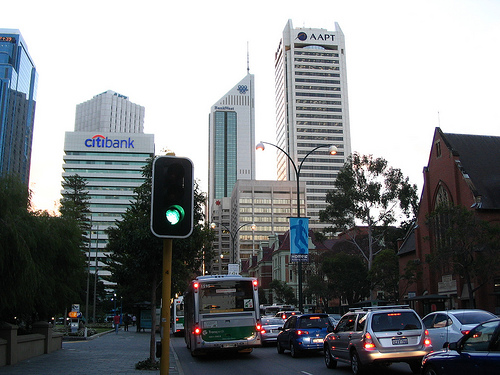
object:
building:
[208, 41, 256, 229]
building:
[396, 111, 500, 319]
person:
[113, 312, 120, 335]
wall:
[237, 107, 253, 174]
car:
[275, 313, 336, 359]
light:
[150, 155, 195, 239]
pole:
[256, 141, 338, 315]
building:
[0, 28, 40, 190]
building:
[229, 179, 306, 264]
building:
[275, 17, 355, 239]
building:
[73, 89, 146, 133]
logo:
[84, 134, 135, 148]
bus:
[179, 273, 262, 358]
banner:
[286, 216, 311, 263]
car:
[323, 304, 434, 375]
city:
[0, 0, 500, 375]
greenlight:
[169, 210, 178, 219]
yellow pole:
[158, 238, 173, 375]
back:
[192, 274, 263, 349]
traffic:
[173, 268, 500, 374]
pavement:
[176, 357, 289, 375]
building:
[56, 130, 155, 301]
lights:
[195, 324, 262, 335]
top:
[210, 73, 255, 106]